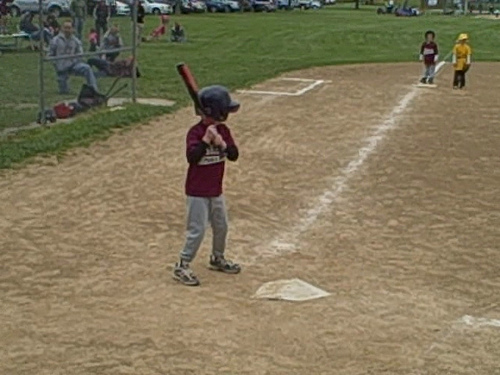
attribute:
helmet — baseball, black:
[198, 83, 235, 102]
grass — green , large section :
[144, 8, 496, 63]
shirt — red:
[181, 112, 239, 199]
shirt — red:
[185, 122, 238, 198]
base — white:
[250, 274, 331, 303]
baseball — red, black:
[175, 59, 224, 157]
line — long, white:
[250, 49, 484, 296]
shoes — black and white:
[168, 257, 244, 288]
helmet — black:
[193, 85, 240, 117]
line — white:
[251, 50, 452, 270]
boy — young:
[172, 84, 241, 285]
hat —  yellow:
[456, 29, 473, 64]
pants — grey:
[177, 192, 228, 259]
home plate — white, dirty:
[249, 270, 336, 305]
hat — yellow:
[456, 31, 466, 38]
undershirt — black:
[182, 121, 241, 169]